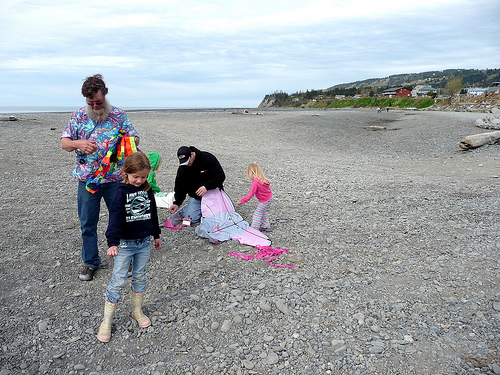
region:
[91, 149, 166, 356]
girl wearing the boots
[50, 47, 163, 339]
Man holding the kite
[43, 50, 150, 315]
man with the grey beard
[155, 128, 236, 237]
man kneeling on the ground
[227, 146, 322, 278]
little girl in pink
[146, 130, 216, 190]
the man in black hat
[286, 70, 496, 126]
houses in the back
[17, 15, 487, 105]
the vast blue sky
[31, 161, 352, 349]
area of groun they are on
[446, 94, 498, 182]
logs on the side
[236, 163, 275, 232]
little girl in pink shirt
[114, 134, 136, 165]
rainbow colored towel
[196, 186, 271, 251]
grey and pink elephant kite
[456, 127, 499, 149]
worn piece of driftwood in the background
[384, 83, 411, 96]
large red building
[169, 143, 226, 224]
person wearing black cap knealing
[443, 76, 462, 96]
large light green tree on the slope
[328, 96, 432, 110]
patch of green grass in the background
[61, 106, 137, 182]
blue and pink shirt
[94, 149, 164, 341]
girl with navy blue sweatshirt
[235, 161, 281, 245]
A young girl looking at the ground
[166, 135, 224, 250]
A man looking at the kite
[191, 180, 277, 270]
A kite on the ground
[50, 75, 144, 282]
A man looking at the ground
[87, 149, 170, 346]
A young girl looking at the ground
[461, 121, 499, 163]
Part of a log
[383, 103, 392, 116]
A person in the distance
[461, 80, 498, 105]
A building on a hill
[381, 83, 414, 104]
A red building on a hill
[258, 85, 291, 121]
A cliff over the ocean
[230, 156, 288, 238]
child in pink shirt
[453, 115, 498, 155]
a large log of driftwood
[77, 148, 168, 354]
child wearing black shirt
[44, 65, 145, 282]
man with grey beard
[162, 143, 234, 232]
man with black shirt on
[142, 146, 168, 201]
child in green sweater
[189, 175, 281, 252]
kite shaped like an elephant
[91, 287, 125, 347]
green children's rubber boot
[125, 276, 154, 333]
green children's rubber boot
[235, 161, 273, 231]
child with blonde hair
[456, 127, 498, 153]
large piece of driftwood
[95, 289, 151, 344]
multi-colored pastel boots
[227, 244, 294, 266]
hot pink kite tassels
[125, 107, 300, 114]
large body of water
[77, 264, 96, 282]
sandals worn with socks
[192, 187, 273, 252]
large dumbo kite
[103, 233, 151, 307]
little girl's blue jeans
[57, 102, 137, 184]
large man's colorful tie-dyed shirt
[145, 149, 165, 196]
small green hooded sweatshirt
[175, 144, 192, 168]
black and white baseball hat